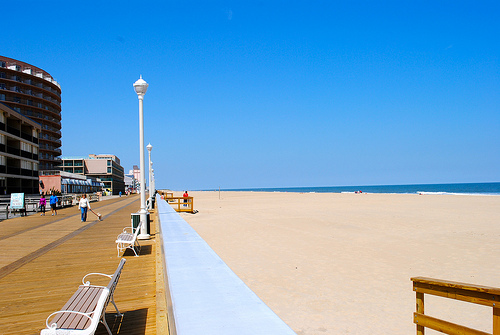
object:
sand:
[157, 189, 499, 334]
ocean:
[189, 182, 499, 195]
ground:
[0, 191, 499, 335]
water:
[176, 181, 498, 196]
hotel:
[0, 57, 63, 197]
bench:
[41, 258, 125, 335]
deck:
[0, 193, 170, 335]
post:
[138, 96, 147, 212]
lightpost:
[132, 74, 150, 240]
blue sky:
[1, 0, 498, 192]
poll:
[133, 73, 149, 100]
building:
[0, 105, 41, 199]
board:
[157, 196, 298, 335]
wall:
[156, 195, 298, 335]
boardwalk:
[0, 193, 171, 335]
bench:
[115, 221, 142, 257]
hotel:
[54, 154, 124, 197]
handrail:
[410, 277, 500, 335]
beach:
[166, 190, 499, 335]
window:
[21, 141, 32, 152]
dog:
[97, 212, 103, 221]